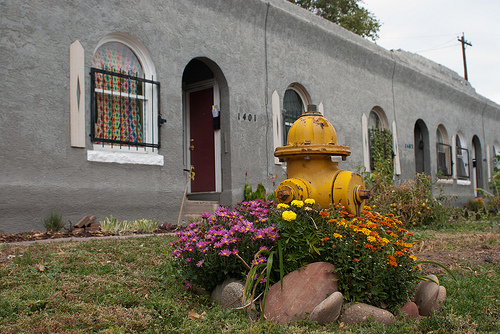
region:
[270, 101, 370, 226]
a yellow fire hydrant in a yard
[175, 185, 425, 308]
a flower garden around the fire hydrant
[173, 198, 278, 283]
purple flowers next to the hydrant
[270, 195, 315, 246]
yellow marigolds in the garden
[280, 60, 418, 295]
orange and yellow flowers in front of a house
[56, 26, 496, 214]
the windows are arched on the house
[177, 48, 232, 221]
the doorway entrance is arched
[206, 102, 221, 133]
a black mailbox full of mail on the wall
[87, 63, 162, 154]
bars are on the window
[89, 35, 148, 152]
colorful curtains can be seen in the window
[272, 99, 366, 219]
yellow fire hydrant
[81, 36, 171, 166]
black bars on window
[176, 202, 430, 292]
yellow orange and purple flowers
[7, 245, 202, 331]
green and brown ground vegitation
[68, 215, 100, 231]
bricks piled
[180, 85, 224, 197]
maroon door is closed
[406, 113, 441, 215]
archway in grey stone building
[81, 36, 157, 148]
multicolored curtain in window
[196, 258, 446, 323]
rocks around flower garden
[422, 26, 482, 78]
electrical pole standing behind building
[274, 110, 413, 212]
the hydrant is yellow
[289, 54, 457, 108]
the walls are grey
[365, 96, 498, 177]
the windows are oval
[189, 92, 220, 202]
the door is red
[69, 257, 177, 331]
the grass is green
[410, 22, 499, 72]
the sky is cloudy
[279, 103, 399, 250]
the fire hydrant is mettalic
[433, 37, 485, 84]
the pole is made of wood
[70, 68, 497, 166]
there are six windows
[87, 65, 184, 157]
the window has mettalic bars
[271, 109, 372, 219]
Weathered looking hydrant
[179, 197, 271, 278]
Cluster of pink flowers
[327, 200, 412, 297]
Mixture of yellow and orange flowers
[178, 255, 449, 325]
Decorative rocks in front of flowers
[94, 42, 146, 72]
Colorful curtain in window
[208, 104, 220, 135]
Mail in mail box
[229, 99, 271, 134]
Numbers on house are black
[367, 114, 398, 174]
Greenery covering front window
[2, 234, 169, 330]
Brown spotted grass in front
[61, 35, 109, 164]
White shutter near window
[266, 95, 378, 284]
Yellow fire hydrant on the ground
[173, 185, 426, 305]
Flowers around the fire hydrant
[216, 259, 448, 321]
Rocks around the fire hydrant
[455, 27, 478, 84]
Electricity pole behind the buildings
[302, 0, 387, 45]
Tree leaves in the background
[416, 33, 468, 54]
Electric wires in the air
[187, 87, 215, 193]
Red door in the building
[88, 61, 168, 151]
Metal bars over the window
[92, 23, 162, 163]
Window with white frames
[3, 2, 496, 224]
Gray building behind the hydrant